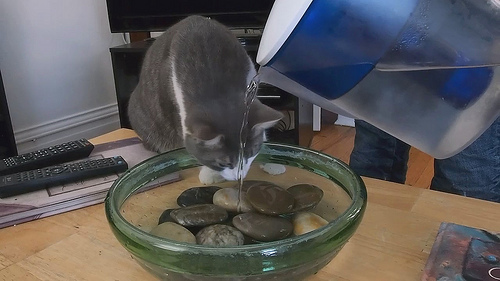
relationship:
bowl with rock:
[101, 140, 368, 273] [289, 181, 322, 208]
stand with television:
[105, 36, 342, 153] [102, 1, 280, 36]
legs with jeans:
[346, 120, 497, 196] [338, 102, 498, 201]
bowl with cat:
[101, 140, 368, 273] [127, 15, 284, 182]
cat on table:
[120, 23, 300, 193] [341, 148, 436, 271]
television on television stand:
[106, 0, 276, 34] [109, 33, 313, 148]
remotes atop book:
[2, 138, 122, 185] [4, 193, 96, 210]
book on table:
[415, 210, 494, 279] [6, 128, 498, 278]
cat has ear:
[128, 14, 286, 183] [246, 94, 283, 136]